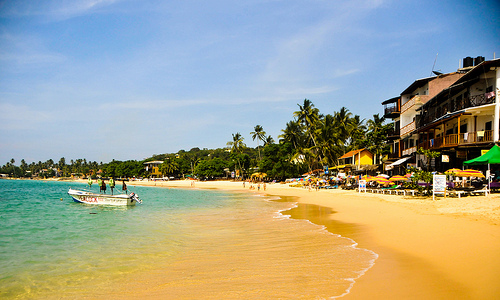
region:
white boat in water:
[62, 176, 162, 235]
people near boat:
[85, 178, 140, 195]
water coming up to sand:
[180, 186, 292, 282]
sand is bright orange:
[355, 201, 468, 289]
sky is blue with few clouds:
[44, 31, 211, 137]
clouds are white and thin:
[23, 34, 173, 116]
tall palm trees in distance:
[210, 118, 309, 155]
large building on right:
[398, 73, 492, 138]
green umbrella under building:
[446, 119, 498, 169]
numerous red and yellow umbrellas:
[352, 167, 477, 197]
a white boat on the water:
[64, 186, 142, 209]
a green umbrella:
[462, 140, 498, 166]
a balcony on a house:
[423, 103, 496, 156]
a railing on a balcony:
[432, 127, 494, 148]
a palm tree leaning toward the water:
[297, 101, 331, 174]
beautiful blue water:
[0, 181, 210, 291]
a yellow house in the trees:
[147, 160, 164, 181]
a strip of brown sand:
[244, 199, 490, 298]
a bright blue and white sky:
[0, 1, 495, 159]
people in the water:
[94, 176, 130, 193]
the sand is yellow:
[13, 175, 499, 298]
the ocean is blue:
[2, 178, 243, 298]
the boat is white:
[54, 182, 139, 212]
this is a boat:
[68, 185, 144, 210]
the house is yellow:
[326, 147, 374, 175]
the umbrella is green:
[458, 135, 498, 199]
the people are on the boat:
[88, 172, 138, 197]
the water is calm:
[0, 176, 368, 298]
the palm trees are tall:
[221, 92, 392, 188]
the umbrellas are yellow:
[357, 164, 486, 194]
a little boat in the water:
[66, 189, 133, 212]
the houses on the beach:
[318, 46, 488, 181]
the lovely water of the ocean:
[6, 177, 193, 299]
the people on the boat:
[96, 175, 126, 192]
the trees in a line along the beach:
[6, 105, 363, 177]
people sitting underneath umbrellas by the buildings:
[309, 170, 484, 203]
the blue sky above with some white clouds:
[11, 4, 499, 144]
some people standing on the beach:
[240, 174, 265, 191]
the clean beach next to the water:
[203, 178, 492, 298]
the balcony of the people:
[428, 125, 493, 145]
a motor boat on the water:
[61, 189, 143, 206]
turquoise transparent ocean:
[0, 180, 47, 235]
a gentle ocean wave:
[295, 208, 385, 296]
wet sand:
[311, 201, 334, 221]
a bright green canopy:
[466, 146, 498, 168]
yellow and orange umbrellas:
[366, 173, 411, 185]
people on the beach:
[244, 182, 276, 195]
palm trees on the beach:
[225, 98, 337, 156]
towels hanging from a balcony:
[462, 127, 490, 142]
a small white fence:
[366, 187, 412, 194]